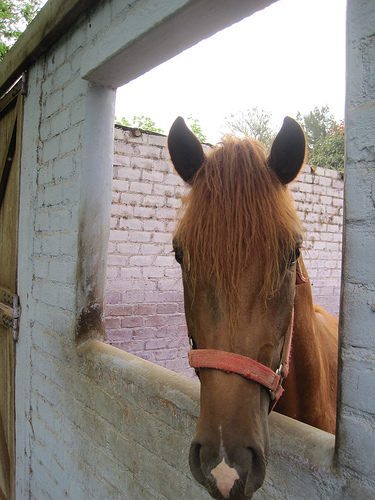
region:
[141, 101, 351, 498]
horse looking at a camera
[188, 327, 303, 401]
bridle of a horse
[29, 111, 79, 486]
white brick wall of horse stable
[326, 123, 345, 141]
red flowers on bushes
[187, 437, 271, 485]
nose of a horse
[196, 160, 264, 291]
hair of a horse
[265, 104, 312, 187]
left ear of a horse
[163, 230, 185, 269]
right eye of a horse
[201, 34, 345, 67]
white sunny sky in the background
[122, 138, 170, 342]
red brick wall of horse's stable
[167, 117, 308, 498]
The head of a horse.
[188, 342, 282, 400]
The strap is on its nose.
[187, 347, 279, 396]
The strap is red.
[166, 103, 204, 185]
The ears are sticking up.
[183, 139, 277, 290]
The horses hair hangs down.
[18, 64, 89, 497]
The brick wall is white.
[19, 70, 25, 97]
The hinge of a door.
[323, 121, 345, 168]
The trees over the wall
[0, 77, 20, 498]
The stall door is wooden.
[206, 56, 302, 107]
The sun is shining bright.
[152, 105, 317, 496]
brown horse with hair in its eyes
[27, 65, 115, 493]
old white brick wall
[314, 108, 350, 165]
red flowers on a tall bush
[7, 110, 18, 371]
wooden stall door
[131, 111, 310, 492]
horse in a stall made of white brick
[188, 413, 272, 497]
muzzle of a horse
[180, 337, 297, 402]
red muzzle on a horse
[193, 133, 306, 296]
brown mane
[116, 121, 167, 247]
dirty white brick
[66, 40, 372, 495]
window of a brick stall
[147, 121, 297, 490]
a brown horse head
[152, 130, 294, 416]
horse with red bridle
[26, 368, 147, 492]
white brick wall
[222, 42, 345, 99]
bright sunny sky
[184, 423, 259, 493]
horse nose with white spot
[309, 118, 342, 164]
red flowers growing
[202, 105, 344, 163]
trees sticking up over wall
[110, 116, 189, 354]
brick horse stall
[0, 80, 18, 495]
brown barn door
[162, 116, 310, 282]
brown horse bangs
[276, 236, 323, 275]
a horses right eye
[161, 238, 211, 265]
a horses left eye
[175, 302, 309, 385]
a red bridle is on a horse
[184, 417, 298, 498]
a white marking on horse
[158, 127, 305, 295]
hair is in horses face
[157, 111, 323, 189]
the horse has two ears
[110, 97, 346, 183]
green trees are behind horse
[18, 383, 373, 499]
a brick window building horse has head through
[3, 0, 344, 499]
brown horse with head sticking out of brick window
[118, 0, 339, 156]
a cloudy sky is overhead of horse